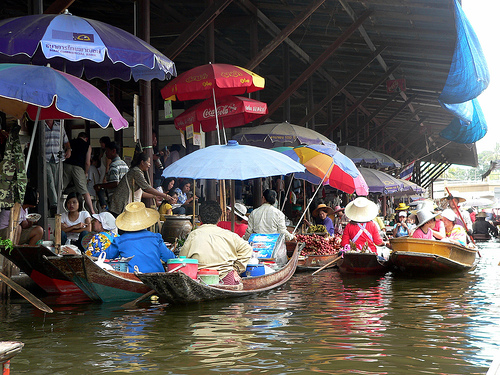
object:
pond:
[0, 228, 500, 375]